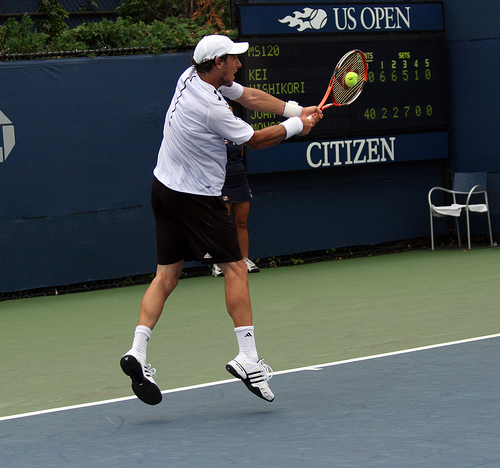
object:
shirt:
[153, 65, 254, 197]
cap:
[193, 33, 249, 64]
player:
[120, 33, 324, 395]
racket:
[307, 49, 368, 120]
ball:
[344, 70, 359, 86]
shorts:
[151, 172, 243, 265]